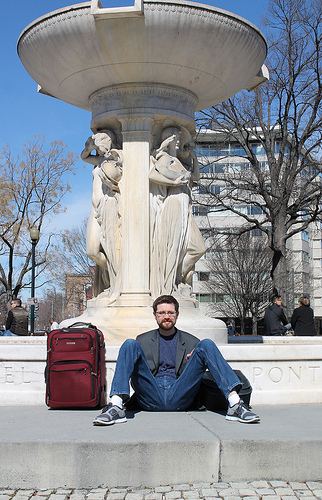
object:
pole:
[28, 237, 35, 334]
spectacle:
[0, 0, 322, 499]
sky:
[0, 0, 322, 307]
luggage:
[43, 319, 107, 412]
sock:
[227, 388, 240, 407]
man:
[91, 293, 261, 427]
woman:
[290, 294, 317, 336]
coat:
[289, 305, 315, 337]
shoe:
[224, 398, 261, 425]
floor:
[0, 388, 322, 445]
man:
[262, 293, 291, 338]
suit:
[261, 304, 289, 336]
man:
[2, 297, 29, 335]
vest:
[4, 305, 29, 336]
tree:
[0, 132, 87, 324]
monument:
[15, 0, 271, 347]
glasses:
[154, 309, 178, 317]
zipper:
[91, 370, 97, 376]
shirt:
[153, 332, 178, 379]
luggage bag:
[43, 319, 109, 412]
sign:
[26, 296, 39, 306]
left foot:
[224, 398, 261, 424]